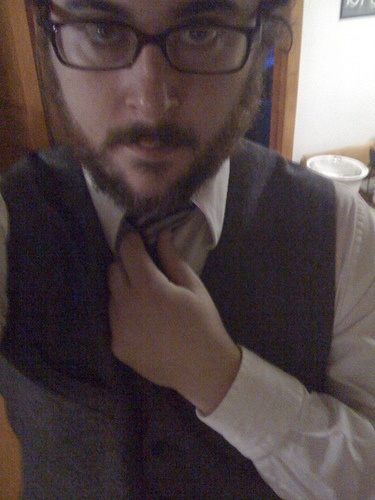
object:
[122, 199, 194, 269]
tie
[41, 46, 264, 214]
beard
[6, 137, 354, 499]
vest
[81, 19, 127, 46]
eyeball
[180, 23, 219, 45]
eyeball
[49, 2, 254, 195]
face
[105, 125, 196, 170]
mustache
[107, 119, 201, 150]
brown mustache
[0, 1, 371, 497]
guy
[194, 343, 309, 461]
white cuff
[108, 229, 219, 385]
hand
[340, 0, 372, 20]
mirror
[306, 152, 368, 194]
crockpot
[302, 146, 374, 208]
table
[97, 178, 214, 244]
neck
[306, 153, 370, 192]
cup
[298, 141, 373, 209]
desk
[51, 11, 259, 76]
glasses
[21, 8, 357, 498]
man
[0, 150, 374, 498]
shirt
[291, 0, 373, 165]
wall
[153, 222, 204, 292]
thumb